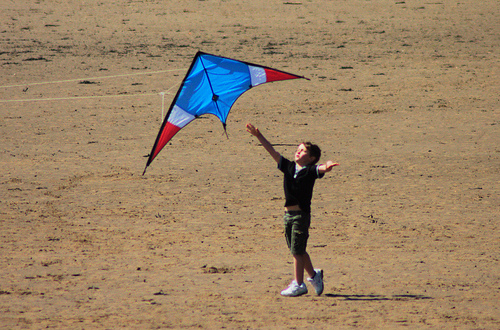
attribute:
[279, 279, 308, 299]
shoe — white, boys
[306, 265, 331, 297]
shoe — white, boys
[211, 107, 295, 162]
hand — outstretched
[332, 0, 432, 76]
dirt — distant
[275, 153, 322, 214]
shirt — black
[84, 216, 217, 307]
dirt — brown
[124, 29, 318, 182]
kite — triangular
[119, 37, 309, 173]
kite — red, white, blue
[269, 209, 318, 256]
shorts — boys, green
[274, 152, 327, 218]
shirt — black, boys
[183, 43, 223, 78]
part — top